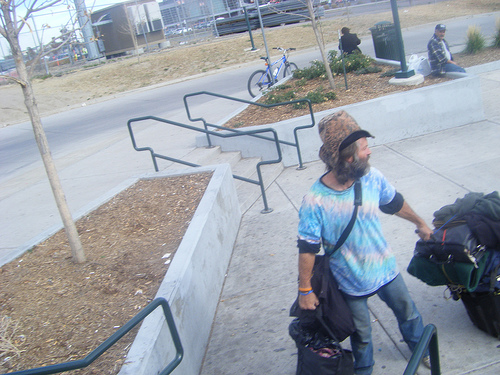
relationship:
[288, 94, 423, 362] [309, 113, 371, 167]
man with hat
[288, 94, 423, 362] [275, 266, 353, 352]
man with bag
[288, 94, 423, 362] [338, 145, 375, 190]
man has beard